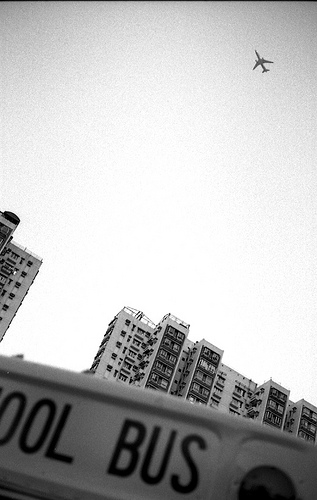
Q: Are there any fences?
A: No, there are no fences.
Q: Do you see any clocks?
A: No, there are no clocks.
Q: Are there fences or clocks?
A: No, there are no clocks or fences.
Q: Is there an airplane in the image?
A: Yes, there is an airplane.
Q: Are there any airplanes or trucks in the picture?
A: Yes, there is an airplane.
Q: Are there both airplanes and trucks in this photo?
A: No, there is an airplane but no trucks.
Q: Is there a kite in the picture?
A: No, there are no kites.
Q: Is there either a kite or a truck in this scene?
A: No, there are no kites or trucks.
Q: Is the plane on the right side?
A: Yes, the plane is on the right of the image.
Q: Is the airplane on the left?
A: No, the airplane is on the right of the image.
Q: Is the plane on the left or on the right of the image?
A: The plane is on the right of the image.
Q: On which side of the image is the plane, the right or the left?
A: The plane is on the right of the image.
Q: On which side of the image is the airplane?
A: The airplane is on the right of the image.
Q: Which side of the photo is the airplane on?
A: The airplane is on the right of the image.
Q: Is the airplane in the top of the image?
A: Yes, the airplane is in the top of the image.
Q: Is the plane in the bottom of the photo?
A: No, the plane is in the top of the image.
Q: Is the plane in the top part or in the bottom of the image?
A: The plane is in the top of the image.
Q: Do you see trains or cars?
A: No, there are no cars or trains.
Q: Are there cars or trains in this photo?
A: No, there are no cars or trains.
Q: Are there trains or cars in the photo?
A: No, there are no cars or trains.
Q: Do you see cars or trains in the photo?
A: No, there are no cars or trains.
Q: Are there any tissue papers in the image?
A: No, there are no tissue papers.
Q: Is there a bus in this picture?
A: Yes, there is a bus.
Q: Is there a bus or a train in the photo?
A: Yes, there is a bus.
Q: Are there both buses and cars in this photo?
A: No, there is a bus but no cars.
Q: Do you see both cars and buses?
A: No, there is a bus but no cars.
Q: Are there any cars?
A: No, there are no cars.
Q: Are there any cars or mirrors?
A: No, there are no cars or mirrors.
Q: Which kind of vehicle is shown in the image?
A: The vehicle is a bus.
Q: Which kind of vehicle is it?
A: The vehicle is a bus.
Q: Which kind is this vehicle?
A: This is a bus.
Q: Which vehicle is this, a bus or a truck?
A: This is a bus.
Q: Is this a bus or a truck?
A: This is a bus.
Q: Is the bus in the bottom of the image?
A: Yes, the bus is in the bottom of the image.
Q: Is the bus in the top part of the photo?
A: No, the bus is in the bottom of the image.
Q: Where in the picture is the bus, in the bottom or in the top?
A: The bus is in the bottom of the image.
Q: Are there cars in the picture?
A: No, there are no cars.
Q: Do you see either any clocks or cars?
A: No, there are no cars or clocks.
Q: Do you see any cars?
A: No, there are no cars.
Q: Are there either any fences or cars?
A: No, there are no cars or fences.